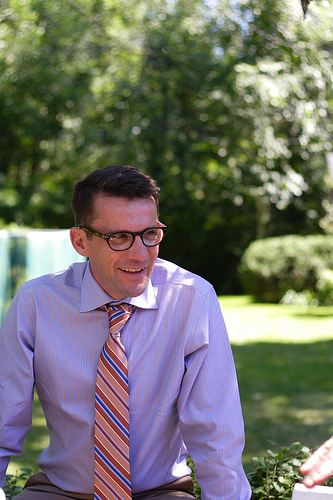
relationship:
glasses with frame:
[79, 218, 172, 252] [74, 225, 108, 243]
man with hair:
[4, 140, 267, 497] [66, 154, 165, 225]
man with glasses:
[4, 140, 267, 497] [79, 218, 172, 252]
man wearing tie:
[4, 140, 267, 497] [88, 300, 142, 499]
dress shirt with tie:
[3, 252, 257, 499] [88, 300, 142, 499]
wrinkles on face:
[98, 251, 116, 279] [98, 206, 163, 295]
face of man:
[98, 206, 163, 295] [4, 140, 267, 497]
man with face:
[4, 140, 267, 497] [98, 206, 163, 295]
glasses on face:
[79, 218, 172, 252] [98, 206, 163, 295]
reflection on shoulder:
[159, 256, 176, 279] [153, 261, 230, 319]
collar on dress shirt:
[75, 263, 171, 323] [3, 252, 257, 499]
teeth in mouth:
[119, 268, 152, 273] [115, 261, 151, 278]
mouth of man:
[115, 261, 151, 278] [4, 140, 267, 497]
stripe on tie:
[98, 348, 129, 386] [88, 300, 142, 499]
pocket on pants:
[170, 475, 196, 491] [7, 470, 200, 500]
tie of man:
[88, 300, 142, 499] [4, 140, 267, 497]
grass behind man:
[215, 297, 326, 470] [4, 140, 267, 497]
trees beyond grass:
[6, 2, 326, 218] [215, 297, 326, 470]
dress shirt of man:
[3, 252, 257, 499] [4, 140, 267, 497]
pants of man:
[7, 470, 200, 500] [4, 140, 267, 497]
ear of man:
[67, 225, 93, 258] [4, 140, 267, 497]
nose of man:
[123, 237, 154, 263] [4, 140, 267, 497]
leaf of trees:
[200, 24, 207, 44] [6, 2, 326, 218]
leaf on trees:
[200, 24, 207, 44] [6, 2, 326, 218]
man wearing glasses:
[4, 140, 267, 497] [79, 218, 172, 252]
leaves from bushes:
[287, 261, 304, 272] [234, 225, 332, 300]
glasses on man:
[79, 218, 172, 252] [4, 140, 267, 497]